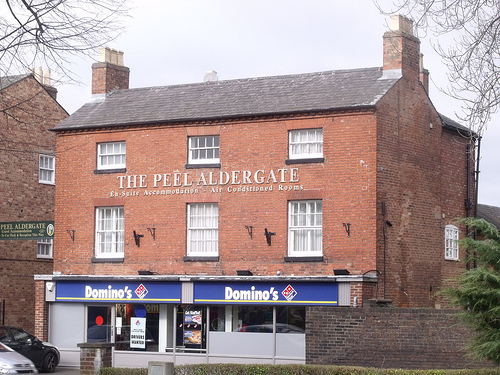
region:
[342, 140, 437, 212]
a red brick building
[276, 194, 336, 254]
white curtains covering a window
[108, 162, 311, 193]
white letters on the side of a building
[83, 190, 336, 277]
three windows on the side of a building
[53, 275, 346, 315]
a blue and white sign on a building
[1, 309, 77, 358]
a car parked in front of a building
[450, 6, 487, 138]
a tree with no leaves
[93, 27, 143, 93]
a chimney on top of a building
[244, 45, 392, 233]
a building with a shingled roof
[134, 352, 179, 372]
a garbage can by a hedge bush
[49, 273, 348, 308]
domino's pizza sign on building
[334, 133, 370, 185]
fascade of a brick building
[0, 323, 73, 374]
small cars parked on the street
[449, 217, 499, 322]
part of a green bush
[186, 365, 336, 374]
top of a hedgeway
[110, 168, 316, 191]
letters of the name of a building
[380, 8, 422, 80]
chimney stack on top of a building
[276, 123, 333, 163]
window with curtains covering it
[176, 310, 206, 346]
marketing sign for Domino's pizza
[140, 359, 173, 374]
trash can on a sidewalk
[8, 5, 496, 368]
the buildings consist of red brick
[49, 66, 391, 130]
a slate roof is on the hotel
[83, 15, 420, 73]
six fireplaces are in the hotel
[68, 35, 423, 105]
two chimneys are on the building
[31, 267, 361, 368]
a pizza restaurant is on the first floor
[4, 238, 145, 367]
cars are parked in front of the building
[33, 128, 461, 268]
the building's windows have white mullions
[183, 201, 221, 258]
the window has white curtains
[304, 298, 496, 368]
a brick wall is to the side of the hotel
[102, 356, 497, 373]
a hedge is in front of the building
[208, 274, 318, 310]
blue sign on front of building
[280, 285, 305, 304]
small blue and red logo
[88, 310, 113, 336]
red spot on window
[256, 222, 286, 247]
black frame on wall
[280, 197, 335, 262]
large white window on front of building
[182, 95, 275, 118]
slanted gray roof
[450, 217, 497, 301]
tall tree beside wall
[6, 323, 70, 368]
car parked in front of store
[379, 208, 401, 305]
black electrical cord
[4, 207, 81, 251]
green sign between building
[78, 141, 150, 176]
window on the building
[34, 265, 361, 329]
the sign is blue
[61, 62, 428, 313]
building made of bricks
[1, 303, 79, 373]
cars parked next to the building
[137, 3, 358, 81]
the sky is cloudy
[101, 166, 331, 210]
words on the building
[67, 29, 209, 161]
chimney on the building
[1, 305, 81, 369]
the car is black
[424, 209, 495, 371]
tree next to the building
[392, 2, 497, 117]
tree has no leaves